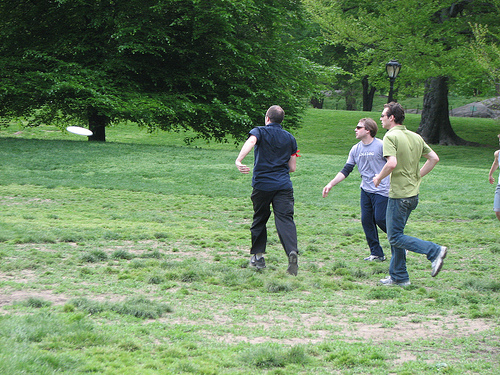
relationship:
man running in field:
[235, 105, 299, 278] [0, 105, 497, 374]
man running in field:
[322, 117, 393, 263] [0, 105, 497, 374]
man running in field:
[372, 101, 448, 288] [0, 105, 497, 374]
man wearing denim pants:
[372, 101, 448, 288] [379, 193, 441, 284]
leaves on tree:
[82, 21, 309, 162] [138, 39, 320, 107]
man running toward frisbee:
[235, 105, 299, 278] [55, 107, 106, 173]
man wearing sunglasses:
[319, 118, 389, 263] [352, 121, 373, 138]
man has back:
[235, 105, 299, 278] [253, 122, 295, 187]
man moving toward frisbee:
[235, 105, 299, 278] [63, 123, 93, 138]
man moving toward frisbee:
[322, 117, 393, 263] [63, 123, 93, 138]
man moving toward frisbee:
[372, 101, 448, 288] [63, 123, 93, 138]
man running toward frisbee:
[235, 105, 299, 278] [60, 125, 94, 136]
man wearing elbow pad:
[322, 117, 393, 263] [338, 164, 353, 179]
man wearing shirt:
[235, 105, 299, 278] [250, 126, 300, 194]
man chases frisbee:
[235, 105, 299, 278] [52, 114, 95, 148]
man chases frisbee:
[371, 102, 449, 289] [52, 114, 95, 148]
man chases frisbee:
[319, 118, 389, 263] [52, 114, 95, 148]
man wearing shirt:
[371, 102, 449, 289] [246, 122, 296, 192]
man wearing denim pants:
[371, 102, 449, 289] [386, 195, 441, 283]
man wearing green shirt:
[371, 102, 449, 289] [379, 120, 431, 198]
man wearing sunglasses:
[371, 102, 449, 289] [378, 112, 390, 119]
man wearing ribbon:
[244, 102, 301, 274] [291, 150, 301, 157]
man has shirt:
[372, 101, 448, 288] [377, 135, 418, 176]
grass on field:
[18, 140, 225, 370] [0, 105, 497, 374]